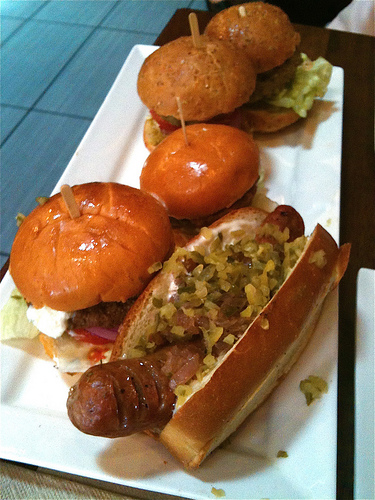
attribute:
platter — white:
[1, 44, 345, 499]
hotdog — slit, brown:
[70, 206, 352, 471]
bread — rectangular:
[178, 226, 374, 475]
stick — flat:
[60, 183, 85, 216]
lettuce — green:
[277, 55, 331, 125]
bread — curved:
[204, 1, 301, 131]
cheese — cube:
[52, 338, 113, 371]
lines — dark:
[5, 469, 22, 499]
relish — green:
[129, 222, 309, 362]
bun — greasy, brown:
[139, 125, 261, 219]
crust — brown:
[139, 32, 257, 152]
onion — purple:
[76, 320, 121, 348]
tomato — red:
[148, 105, 178, 134]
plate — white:
[352, 268, 374, 498]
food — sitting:
[0, 180, 175, 373]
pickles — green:
[209, 261, 248, 286]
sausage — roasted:
[68, 343, 203, 438]